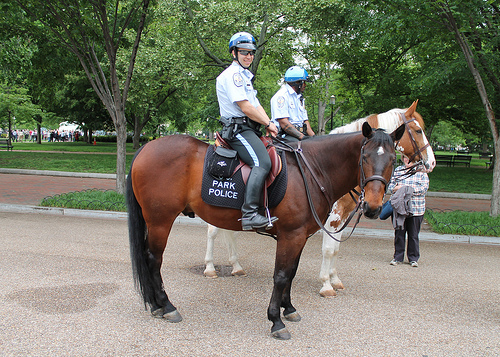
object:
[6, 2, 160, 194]
tree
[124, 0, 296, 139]
tree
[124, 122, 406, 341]
horse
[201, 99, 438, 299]
horse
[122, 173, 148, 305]
tail